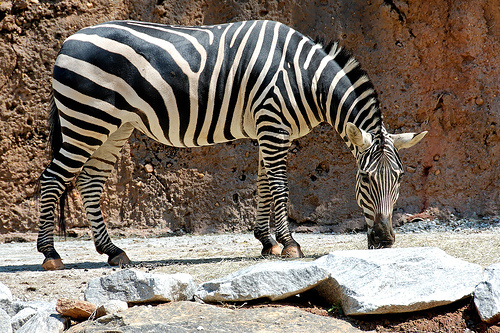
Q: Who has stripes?
A: Zebra.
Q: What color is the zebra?
A: Black and white.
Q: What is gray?
A: Large rocks.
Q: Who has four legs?
A: The zebra.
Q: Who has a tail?
A: A zebra.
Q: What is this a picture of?
A: A zebra.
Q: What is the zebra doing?
A: Eating.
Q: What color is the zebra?
A: White and black.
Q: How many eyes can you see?
A: 2.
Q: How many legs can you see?
A: 4.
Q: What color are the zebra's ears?
A: White.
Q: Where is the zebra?
A: In front of rocks.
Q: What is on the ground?
A: Rocks.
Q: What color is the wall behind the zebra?
A: Red.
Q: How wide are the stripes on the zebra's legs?
A: Narrow.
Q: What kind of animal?
A: Zebra.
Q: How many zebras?
A: One.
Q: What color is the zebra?
A: Black and white.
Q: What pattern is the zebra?
A: Stripes.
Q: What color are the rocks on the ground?
A: Grey.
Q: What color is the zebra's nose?
A: Black.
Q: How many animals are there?
A: 1.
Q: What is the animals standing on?
A: Rocks.